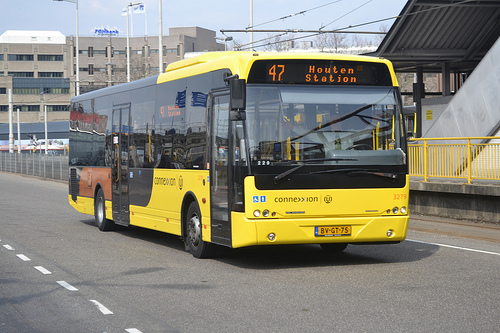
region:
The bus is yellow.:
[39, 67, 417, 270]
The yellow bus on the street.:
[38, 50, 438, 257]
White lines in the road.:
[6, 239, 94, 331]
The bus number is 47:
[256, 52, 303, 87]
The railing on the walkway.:
[406, 129, 498, 185]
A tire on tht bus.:
[178, 197, 216, 264]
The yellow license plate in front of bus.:
[310, 218, 370, 243]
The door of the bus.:
[186, 98, 243, 223]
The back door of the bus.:
[98, 102, 134, 231]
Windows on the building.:
[72, 42, 176, 83]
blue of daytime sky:
[0, 0, 405, 40]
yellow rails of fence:
[411, 134, 498, 182]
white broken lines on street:
[1, 242, 140, 332]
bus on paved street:
[68, 52, 410, 254]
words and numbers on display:
[251, 59, 388, 86]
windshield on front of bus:
[251, 88, 403, 183]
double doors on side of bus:
[109, 104, 132, 227]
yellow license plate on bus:
[314, 224, 351, 237]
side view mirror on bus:
[223, 74, 245, 120]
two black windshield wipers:
[266, 156, 400, 186]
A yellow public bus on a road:
[60, 45, 414, 266]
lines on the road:
[11, 226, 153, 331]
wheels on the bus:
[85, 187, 240, 318]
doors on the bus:
[103, 105, 223, 244]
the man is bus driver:
[286, 108, 380, 162]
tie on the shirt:
[326, 125, 356, 152]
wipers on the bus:
[278, 159, 399, 196]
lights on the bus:
[247, 202, 404, 222]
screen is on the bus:
[257, 59, 394, 106]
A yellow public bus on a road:
[55, 41, 419, 260]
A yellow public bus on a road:
[51, 45, 427, 272]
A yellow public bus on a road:
[60, 45, 428, 265]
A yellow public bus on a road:
[56, 45, 421, 263]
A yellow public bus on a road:
[60, 45, 421, 267]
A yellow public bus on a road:
[57, 47, 422, 257]